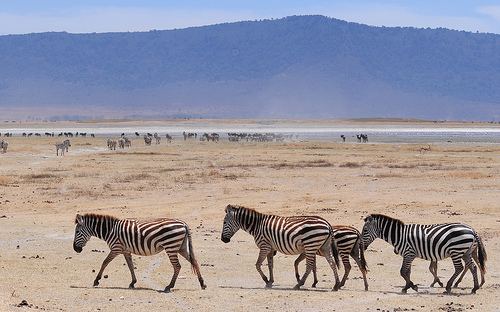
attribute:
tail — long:
[182, 223, 200, 274]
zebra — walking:
[73, 212, 207, 292]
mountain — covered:
[0, 15, 499, 107]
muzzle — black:
[71, 239, 85, 252]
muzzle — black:
[220, 236, 232, 243]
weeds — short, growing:
[0, 159, 495, 203]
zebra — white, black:
[361, 213, 488, 293]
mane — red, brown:
[87, 211, 127, 222]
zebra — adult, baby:
[225, 198, 487, 295]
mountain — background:
[2, 12, 499, 136]